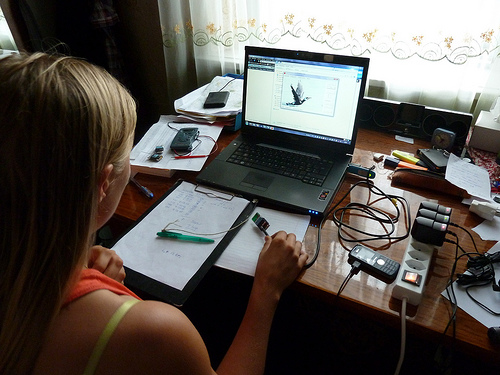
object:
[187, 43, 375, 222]
laptop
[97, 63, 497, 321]
desk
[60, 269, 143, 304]
shirt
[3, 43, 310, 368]
girl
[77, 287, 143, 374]
strap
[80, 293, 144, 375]
bra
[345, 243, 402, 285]
cellphone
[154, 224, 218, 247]
pen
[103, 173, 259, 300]
clip board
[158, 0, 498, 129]
curtain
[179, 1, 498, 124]
window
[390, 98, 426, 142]
station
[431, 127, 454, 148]
clock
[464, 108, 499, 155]
box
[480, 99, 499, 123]
tissues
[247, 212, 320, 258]
cord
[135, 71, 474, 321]
table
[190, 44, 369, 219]
computer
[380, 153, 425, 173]
marker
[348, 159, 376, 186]
plug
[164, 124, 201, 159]
recorder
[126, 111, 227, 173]
paper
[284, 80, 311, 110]
duck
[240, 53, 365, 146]
screen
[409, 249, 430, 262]
plug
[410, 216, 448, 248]
adapters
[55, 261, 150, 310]
top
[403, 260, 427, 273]
outlet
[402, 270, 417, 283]
light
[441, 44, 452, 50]
flowers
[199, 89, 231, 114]
electronics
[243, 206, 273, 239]
charger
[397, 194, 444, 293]
powerstrip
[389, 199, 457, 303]
surge protector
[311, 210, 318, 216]
lights